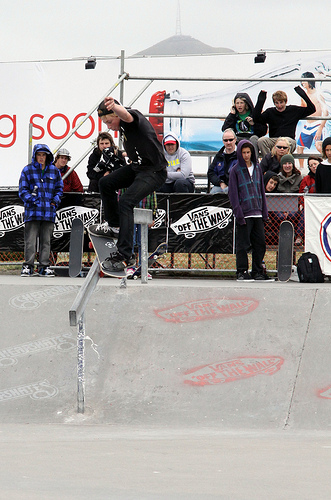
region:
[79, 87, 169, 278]
person doing a skateboard trick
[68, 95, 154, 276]
person is skateboarding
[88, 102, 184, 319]
person doing a trick on a rail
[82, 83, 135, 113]
person wearing a black hat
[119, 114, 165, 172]
person is wearing a black shirt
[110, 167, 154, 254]
person is wearing black pants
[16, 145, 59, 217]
person is wearing a plaid jacket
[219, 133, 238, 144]
person is wearing sun glasses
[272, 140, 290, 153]
person is wearing sun glasses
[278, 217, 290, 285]
skateboard leaning on fence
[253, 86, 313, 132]
Guy is cheering for the skateboarder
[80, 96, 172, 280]
Skateboarder in the middle of a jump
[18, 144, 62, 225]
Guy wearing a plaid jacket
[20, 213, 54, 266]
Guy wearing black jeans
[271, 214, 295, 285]
Skateboard leaning on a fence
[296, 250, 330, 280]
Black backpack on the floor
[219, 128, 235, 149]
Man wearing dark sunglasses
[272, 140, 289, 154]
Woman wearing dark sunglasses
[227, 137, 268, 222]
Guy wearing a purple jacket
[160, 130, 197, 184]
Guy wearing a grey sweater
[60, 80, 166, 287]
Man skateboarding on a rail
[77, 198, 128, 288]
Black skate board on a rail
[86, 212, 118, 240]
White laces on black tennis shoes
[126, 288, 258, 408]
Cement ramp at skateboard park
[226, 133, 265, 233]
Person wearing a hooded jacket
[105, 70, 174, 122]
Metal rails on bleachers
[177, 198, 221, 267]
Sign on a metal fence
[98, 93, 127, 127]
Black baseball hat on backwards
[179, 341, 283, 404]
Advertising on a cement ramp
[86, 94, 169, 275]
Man on a skateboard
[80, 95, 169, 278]
Man riding a skateboard down a rail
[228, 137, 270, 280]
Man in a purple sweatshirt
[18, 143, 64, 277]
Man in a blue plaid shirt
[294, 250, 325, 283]
Black backpack on the ground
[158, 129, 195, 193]
Man wearing a gray sweatshirt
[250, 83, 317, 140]
Man wearing a long sleeved black shirt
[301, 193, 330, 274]
White banner on a fence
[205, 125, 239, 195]
Older man in a black jacket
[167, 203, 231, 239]
White and black Vans logo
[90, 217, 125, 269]
skateboarder has two different shoestrings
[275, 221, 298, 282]
skateboard leaning against fence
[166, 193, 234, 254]
black Vans advertisement on fence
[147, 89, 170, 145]
red bottle cap on sign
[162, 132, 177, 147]
red and white ball cap on spectator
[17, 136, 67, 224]
blue checkered hoodie on spectator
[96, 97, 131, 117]
black ball cap is backwards on skateboarder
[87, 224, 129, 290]
skateboard is riding the rail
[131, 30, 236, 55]
mountain peak in background